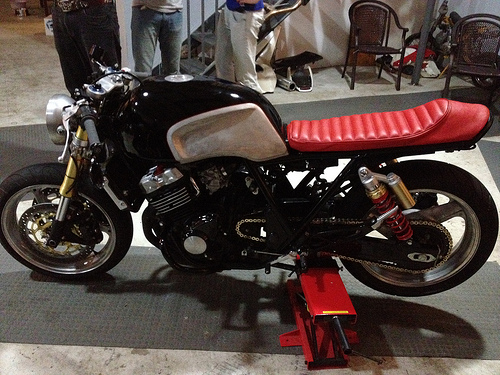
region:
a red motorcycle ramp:
[275, 234, 369, 366]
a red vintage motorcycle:
[0, 46, 498, 308]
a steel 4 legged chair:
[337, 2, 410, 92]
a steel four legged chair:
[442, 11, 499, 104]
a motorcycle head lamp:
[28, 83, 88, 152]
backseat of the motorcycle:
[283, 90, 498, 149]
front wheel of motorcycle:
[0, 154, 155, 280]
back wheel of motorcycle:
[343, 151, 498, 296]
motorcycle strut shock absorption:
[350, 157, 425, 246]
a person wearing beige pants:
[202, 0, 288, 100]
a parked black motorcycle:
[2, 42, 497, 297]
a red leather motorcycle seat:
[287, 97, 489, 150]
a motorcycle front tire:
[0, 163, 132, 279]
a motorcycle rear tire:
[341, 159, 498, 296]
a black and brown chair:
[342, 0, 407, 88]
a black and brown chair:
[439, 13, 499, 103]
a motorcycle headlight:
[45, 92, 75, 144]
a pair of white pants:
[215, 10, 265, 90]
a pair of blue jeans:
[130, 3, 180, 72]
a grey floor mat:
[0, 241, 498, 358]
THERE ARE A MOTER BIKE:
[0, 44, 494, 294]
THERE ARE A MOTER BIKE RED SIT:
[282, 94, 492, 156]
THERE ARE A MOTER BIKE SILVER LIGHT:
[42, 88, 76, 141]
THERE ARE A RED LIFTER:
[273, 243, 390, 371]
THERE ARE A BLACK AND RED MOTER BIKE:
[0, 68, 499, 291]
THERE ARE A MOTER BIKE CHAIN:
[222, 213, 454, 275]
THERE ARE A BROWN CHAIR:
[342, 0, 409, 99]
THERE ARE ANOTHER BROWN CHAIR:
[438, 16, 498, 106]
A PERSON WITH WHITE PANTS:
[206, 0, 267, 90]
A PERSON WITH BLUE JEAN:
[127, 3, 186, 78]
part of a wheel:
[463, 203, 480, 233]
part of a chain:
[407, 226, 427, 241]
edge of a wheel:
[396, 174, 430, 228]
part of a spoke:
[411, 206, 423, 209]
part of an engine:
[232, 230, 249, 269]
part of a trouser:
[252, 62, 260, 84]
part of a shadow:
[378, 328, 382, 333]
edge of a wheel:
[428, 188, 445, 223]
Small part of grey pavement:
[13, 345, 30, 371]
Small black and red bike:
[28, 48, 480, 343]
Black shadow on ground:
[131, 239, 477, 374]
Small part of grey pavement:
[103, 351, 136, 374]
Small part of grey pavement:
[132, 352, 154, 370]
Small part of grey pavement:
[168, 356, 174, 358]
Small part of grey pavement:
[201, 354, 233, 372]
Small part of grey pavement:
[263, 351, 308, 373]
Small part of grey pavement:
[385, 356, 392, 374]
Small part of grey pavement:
[4, 29, 46, 91]